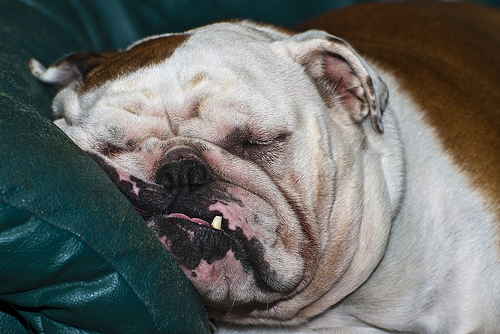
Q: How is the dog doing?
A: Sleeping.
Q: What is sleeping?
A: A dog.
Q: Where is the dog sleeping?
A: Pillow.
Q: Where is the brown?
A: On dog.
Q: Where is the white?
A: On dog.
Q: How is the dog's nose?
A: Black.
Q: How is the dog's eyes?
A: Closed.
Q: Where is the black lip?
A: On dog.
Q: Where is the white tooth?
A: On mouth.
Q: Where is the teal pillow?
A: Under dog.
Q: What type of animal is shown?
A: Dog.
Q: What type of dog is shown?
A: Bull dog.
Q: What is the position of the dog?
A: Laying.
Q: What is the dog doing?
A: Sleeping.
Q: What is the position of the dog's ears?
A: Down.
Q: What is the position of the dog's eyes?
A: Closed.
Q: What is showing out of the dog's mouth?
A: Tooth.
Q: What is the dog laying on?
A: Couch.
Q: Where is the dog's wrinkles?
A: Dog's face.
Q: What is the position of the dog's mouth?
A: Closed.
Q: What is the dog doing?
A: Sleeping.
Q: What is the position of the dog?
A: Laying.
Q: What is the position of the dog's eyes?
A: Closed.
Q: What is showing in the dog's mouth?
A: Tooth.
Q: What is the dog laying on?
A: Couch.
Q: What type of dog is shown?
A: Bull dog.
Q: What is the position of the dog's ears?
A: Down.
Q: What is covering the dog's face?
A: Wrinkles.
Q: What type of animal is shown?
A: Dog.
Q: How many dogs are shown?
A: One.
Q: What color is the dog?
A: Brown and white.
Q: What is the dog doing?
A: Laying.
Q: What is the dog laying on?
A: Chair.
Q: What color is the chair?
A: Green.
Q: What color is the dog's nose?
A: Black.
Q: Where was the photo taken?
A: Near dog.